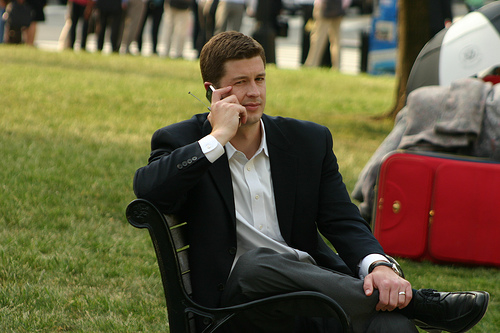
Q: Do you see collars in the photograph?
A: Yes, there is a collar.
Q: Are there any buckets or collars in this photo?
A: Yes, there is a collar.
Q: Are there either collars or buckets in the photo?
A: Yes, there is a collar.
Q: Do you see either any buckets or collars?
A: Yes, there is a collar.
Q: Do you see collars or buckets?
A: Yes, there is a collar.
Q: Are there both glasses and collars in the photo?
A: No, there is a collar but no glasses.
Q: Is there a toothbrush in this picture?
A: No, there are no toothbrushes.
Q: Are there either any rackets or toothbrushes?
A: No, there are no toothbrushes or rackets.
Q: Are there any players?
A: No, there are no players.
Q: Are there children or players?
A: No, there are no players or children.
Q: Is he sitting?
A: Yes, the man is sitting.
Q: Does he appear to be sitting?
A: Yes, the man is sitting.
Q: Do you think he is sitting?
A: Yes, the man is sitting.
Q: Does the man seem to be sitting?
A: Yes, the man is sitting.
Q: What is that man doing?
A: The man is sitting.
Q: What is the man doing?
A: The man is sitting.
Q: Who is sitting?
A: The man is sitting.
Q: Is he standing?
A: No, the man is sitting.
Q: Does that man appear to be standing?
A: No, the man is sitting.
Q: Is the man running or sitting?
A: The man is sitting.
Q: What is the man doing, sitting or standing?
A: The man is sitting.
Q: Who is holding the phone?
A: The man is holding the phone.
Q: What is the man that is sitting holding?
A: The man is holding the phone.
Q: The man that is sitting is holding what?
A: The man is holding the phone.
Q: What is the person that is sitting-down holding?
A: The man is holding the phone.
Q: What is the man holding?
A: The man is holding the phone.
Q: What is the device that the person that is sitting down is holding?
A: The device is a phone.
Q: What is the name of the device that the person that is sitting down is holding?
A: The device is a phone.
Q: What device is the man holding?
A: The man is holding the telephone.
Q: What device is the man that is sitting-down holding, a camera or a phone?
A: The man is holding a phone.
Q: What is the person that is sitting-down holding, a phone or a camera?
A: The man is holding a phone.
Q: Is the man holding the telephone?
A: Yes, the man is holding the telephone.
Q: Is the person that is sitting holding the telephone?
A: Yes, the man is holding the telephone.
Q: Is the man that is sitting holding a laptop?
A: No, the man is holding the telephone.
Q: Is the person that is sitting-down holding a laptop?
A: No, the man is holding the telephone.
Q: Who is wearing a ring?
A: The man is wearing a ring.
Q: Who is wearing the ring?
A: The man is wearing a ring.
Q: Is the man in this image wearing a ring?
A: Yes, the man is wearing a ring.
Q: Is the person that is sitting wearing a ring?
A: Yes, the man is wearing a ring.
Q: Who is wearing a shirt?
A: The man is wearing a shirt.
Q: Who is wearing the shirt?
A: The man is wearing a shirt.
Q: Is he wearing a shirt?
A: Yes, the man is wearing a shirt.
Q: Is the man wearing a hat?
A: No, the man is wearing a shirt.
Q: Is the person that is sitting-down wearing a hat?
A: No, the man is wearing a shirt.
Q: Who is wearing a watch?
A: The man is wearing a watch.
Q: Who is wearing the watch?
A: The man is wearing a watch.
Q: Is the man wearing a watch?
A: Yes, the man is wearing a watch.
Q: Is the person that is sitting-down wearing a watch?
A: Yes, the man is wearing a watch.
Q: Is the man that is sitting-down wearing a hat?
A: No, the man is wearing a watch.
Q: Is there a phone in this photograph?
A: Yes, there is a phone.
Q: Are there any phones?
A: Yes, there is a phone.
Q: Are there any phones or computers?
A: Yes, there is a phone.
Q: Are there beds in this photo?
A: No, there are no beds.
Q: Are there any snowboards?
A: No, there are no snowboards.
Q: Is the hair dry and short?
A: Yes, the hair is dry and short.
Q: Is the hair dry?
A: Yes, the hair is dry.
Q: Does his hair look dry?
A: Yes, the hair is dry.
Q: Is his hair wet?
A: No, the hair is dry.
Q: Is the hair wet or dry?
A: The hair is dry.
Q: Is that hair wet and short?
A: No, the hair is short but dry.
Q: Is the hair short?
A: Yes, the hair is short.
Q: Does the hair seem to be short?
A: Yes, the hair is short.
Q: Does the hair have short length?
A: Yes, the hair is short.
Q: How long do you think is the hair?
A: The hair is short.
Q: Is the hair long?
A: No, the hair is short.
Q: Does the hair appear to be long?
A: No, the hair is short.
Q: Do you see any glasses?
A: No, there are no glasses.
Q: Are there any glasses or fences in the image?
A: No, there are no glasses or fences.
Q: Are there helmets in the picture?
A: No, there are no helmets.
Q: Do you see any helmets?
A: No, there are no helmets.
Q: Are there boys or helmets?
A: No, there are no helmets or boys.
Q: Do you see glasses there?
A: No, there are no glasses.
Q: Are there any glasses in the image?
A: No, there are no glasses.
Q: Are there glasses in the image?
A: No, there are no glasses.